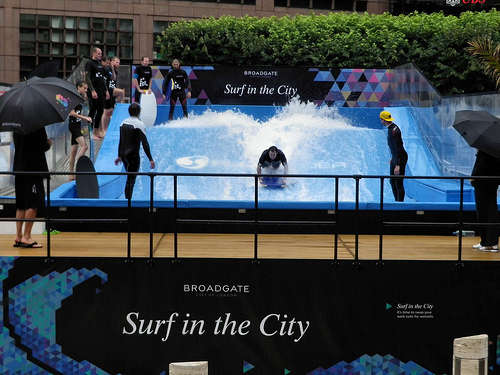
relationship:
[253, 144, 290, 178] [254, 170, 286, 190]
man on surfboard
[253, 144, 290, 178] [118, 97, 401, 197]
man on water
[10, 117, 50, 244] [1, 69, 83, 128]
man holding umbrella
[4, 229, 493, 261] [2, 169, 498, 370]
flooring on platform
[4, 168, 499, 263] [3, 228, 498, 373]
black fencing on platform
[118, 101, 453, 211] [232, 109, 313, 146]
water in waves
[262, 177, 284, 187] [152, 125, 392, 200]
surfboard in water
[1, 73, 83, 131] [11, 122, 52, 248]
umbrella over person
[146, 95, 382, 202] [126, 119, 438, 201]
water for slide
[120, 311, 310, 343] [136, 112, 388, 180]
advertisement displayed on pool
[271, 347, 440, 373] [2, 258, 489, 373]
decoration displayed on sign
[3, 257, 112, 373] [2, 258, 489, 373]
decoration displayed on sign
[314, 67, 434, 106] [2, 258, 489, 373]
decoration displayed on sign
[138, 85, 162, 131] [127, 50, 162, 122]
surfboard next to man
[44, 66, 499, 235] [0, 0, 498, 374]
surf pool inside city